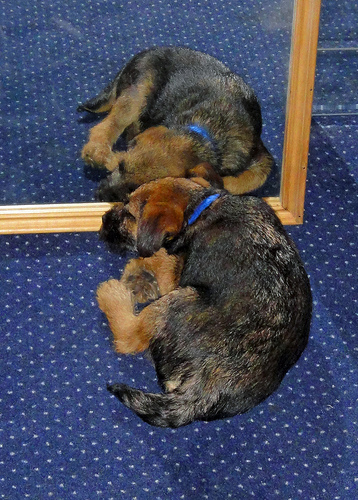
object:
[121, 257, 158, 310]
paws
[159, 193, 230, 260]
fur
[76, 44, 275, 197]
reflection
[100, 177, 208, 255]
head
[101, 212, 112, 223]
nose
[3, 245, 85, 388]
carpet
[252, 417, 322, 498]
floor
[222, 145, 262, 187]
skin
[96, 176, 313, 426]
dog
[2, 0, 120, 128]
carpeting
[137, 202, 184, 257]
ear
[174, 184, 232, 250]
neck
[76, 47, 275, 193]
dog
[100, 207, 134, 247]
mouth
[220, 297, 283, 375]
fur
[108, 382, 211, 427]
tail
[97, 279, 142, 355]
leg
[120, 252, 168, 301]
left paw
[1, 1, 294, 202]
mirror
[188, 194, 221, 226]
collar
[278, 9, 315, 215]
frame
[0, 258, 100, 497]
floor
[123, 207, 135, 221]
left eye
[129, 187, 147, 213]
forehead